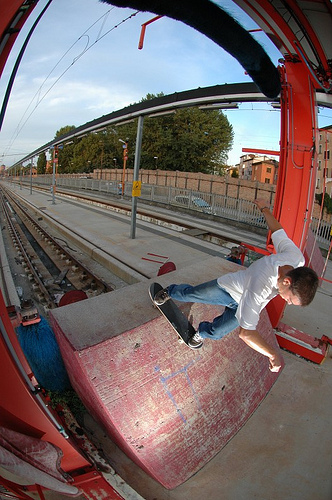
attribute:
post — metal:
[130, 115, 144, 240]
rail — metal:
[105, 84, 257, 128]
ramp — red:
[50, 313, 285, 487]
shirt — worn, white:
[221, 229, 305, 332]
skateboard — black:
[148, 282, 202, 348]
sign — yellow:
[131, 179, 141, 196]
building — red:
[251, 161, 274, 185]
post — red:
[267, 62, 316, 253]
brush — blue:
[17, 317, 72, 398]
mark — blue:
[156, 363, 191, 388]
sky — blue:
[25, 25, 190, 88]